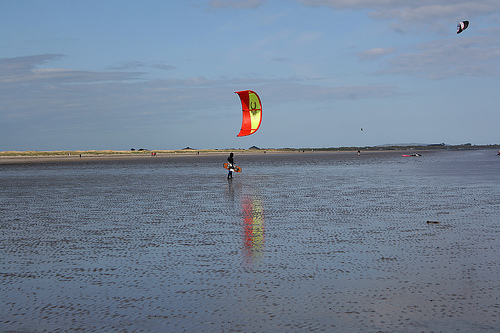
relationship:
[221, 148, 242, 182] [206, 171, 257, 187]
man on sand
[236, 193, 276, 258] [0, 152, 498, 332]
reflection on ocean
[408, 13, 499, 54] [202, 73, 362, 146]
kite in air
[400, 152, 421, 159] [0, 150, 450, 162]
kite on ground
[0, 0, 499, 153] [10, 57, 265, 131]
air with clouds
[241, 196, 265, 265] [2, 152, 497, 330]
reflection on water surface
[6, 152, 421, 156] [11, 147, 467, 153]
shore line of beach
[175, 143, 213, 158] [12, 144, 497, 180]
dune on beach